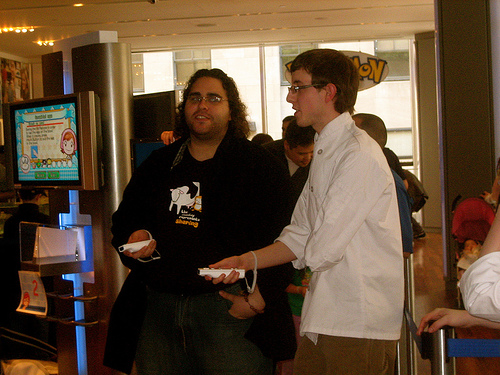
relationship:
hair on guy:
[169, 67, 250, 140] [102, 68, 297, 375]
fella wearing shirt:
[205, 42, 417, 373] [274, 108, 404, 342]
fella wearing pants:
[205, 49, 406, 375] [295, 332, 401, 372]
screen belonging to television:
[13, 100, 80, 182] [5, 105, 102, 187]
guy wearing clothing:
[102, 68, 297, 375] [100, 122, 298, 369]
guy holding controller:
[102, 68, 297, 375] [115, 238, 154, 253]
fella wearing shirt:
[205, 49, 406, 375] [274, 108, 404, 342]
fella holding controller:
[205, 49, 406, 375] [197, 264, 244, 281]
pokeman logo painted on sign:
[281, 45, 389, 89] [283, 47, 390, 93]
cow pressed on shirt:
[165, 170, 205, 228] [165, 136, 225, 321]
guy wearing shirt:
[102, 68, 297, 375] [165, 136, 225, 321]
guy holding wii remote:
[102, 68, 297, 375] [114, 234, 155, 254]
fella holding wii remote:
[205, 49, 406, 375] [194, 264, 247, 280]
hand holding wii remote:
[121, 223, 158, 256] [114, 234, 155, 254]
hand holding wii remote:
[200, 250, 241, 283] [194, 264, 247, 280]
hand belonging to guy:
[121, 223, 158, 256] [102, 68, 297, 375]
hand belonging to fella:
[200, 250, 241, 283] [205, 49, 406, 375]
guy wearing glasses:
[102, 68, 297, 375] [185, 92, 227, 103]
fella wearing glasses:
[205, 49, 406, 375] [286, 80, 323, 96]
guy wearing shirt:
[102, 68, 297, 375] [151, 135, 236, 279]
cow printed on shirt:
[168, 181, 200, 215] [151, 135, 236, 279]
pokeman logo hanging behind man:
[281, 48, 386, 85] [257, 117, 319, 219]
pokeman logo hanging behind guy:
[281, 48, 386, 85] [102, 68, 297, 375]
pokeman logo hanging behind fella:
[281, 48, 386, 85] [205, 49, 406, 375]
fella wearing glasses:
[205, 49, 406, 375] [284, 81, 314, 96]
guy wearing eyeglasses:
[102, 68, 297, 375] [184, 91, 231, 107]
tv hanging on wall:
[8, 93, 103, 195] [433, 43, 477, 133]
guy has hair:
[102, 68, 297, 375] [169, 67, 250, 140]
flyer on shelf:
[2, 273, 54, 317] [0, 243, 111, 373]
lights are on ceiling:
[0, 17, 50, 39] [1, 0, 435, 63]